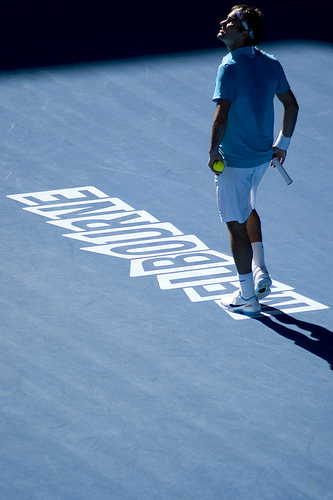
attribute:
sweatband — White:
[230, 10, 253, 34]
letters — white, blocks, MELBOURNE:
[1, 176, 332, 346]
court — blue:
[0, 40, 332, 498]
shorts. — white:
[214, 163, 275, 227]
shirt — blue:
[222, 51, 298, 160]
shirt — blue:
[215, 3, 298, 165]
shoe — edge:
[249, 277, 271, 297]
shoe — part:
[217, 291, 273, 337]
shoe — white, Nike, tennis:
[218, 292, 267, 320]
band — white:
[274, 124, 290, 151]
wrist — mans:
[269, 124, 298, 157]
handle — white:
[264, 145, 299, 188]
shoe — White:
[250, 267, 276, 307]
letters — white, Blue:
[13, 188, 328, 325]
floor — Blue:
[0, 296, 332, 497]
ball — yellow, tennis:
[214, 158, 226, 173]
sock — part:
[238, 278, 244, 283]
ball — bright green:
[212, 160, 224, 172]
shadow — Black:
[253, 298, 331, 367]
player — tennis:
[173, 10, 324, 314]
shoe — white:
[216, 285, 260, 316]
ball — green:
[210, 157, 227, 175]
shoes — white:
[200, 246, 292, 325]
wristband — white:
[272, 129, 294, 150]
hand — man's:
[204, 150, 227, 176]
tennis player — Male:
[207, 5, 299, 315]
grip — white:
[273, 158, 294, 186]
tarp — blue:
[0, 37, 332, 496]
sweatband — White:
[274, 130, 291, 151]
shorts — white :
[216, 159, 269, 224]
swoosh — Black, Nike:
[228, 302, 245, 308]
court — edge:
[15, 77, 294, 362]